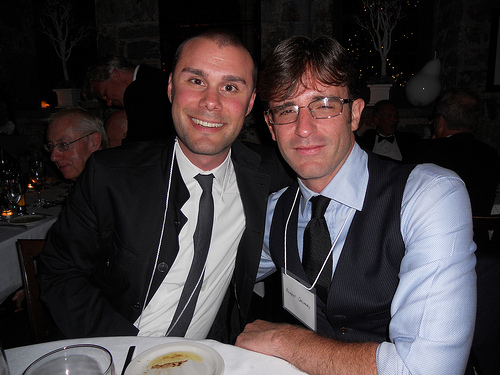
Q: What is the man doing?
A: Smiling.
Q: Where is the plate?
A: On the table.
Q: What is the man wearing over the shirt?
A: A vest.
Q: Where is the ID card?
A: On the man's neck.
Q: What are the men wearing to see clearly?
A: Eyeglasses.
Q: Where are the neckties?
A: On the men's neck.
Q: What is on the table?
A: A plate and utensils.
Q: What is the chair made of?
A: Wood.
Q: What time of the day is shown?
A: Nighttime.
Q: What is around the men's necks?
A: Ties.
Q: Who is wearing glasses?
A: Man on right.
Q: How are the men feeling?
A: Happy.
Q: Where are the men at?
A: A party.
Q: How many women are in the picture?
A: 0.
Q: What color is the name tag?
A: White.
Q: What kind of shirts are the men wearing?
A: Collared shirts.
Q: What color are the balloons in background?
A: White.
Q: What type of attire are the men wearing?
A: Formal.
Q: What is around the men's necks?
A: Tie's.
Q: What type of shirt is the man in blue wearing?
A: A dress shirt.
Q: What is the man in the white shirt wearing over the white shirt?
A: A suit jacket.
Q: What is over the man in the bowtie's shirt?
A: A suit jacket.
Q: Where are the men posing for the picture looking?
A: At the camera.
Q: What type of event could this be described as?
A: A black tie event.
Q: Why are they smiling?
A: They are happy.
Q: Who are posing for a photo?
A: The two men.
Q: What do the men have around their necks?
A: Ties.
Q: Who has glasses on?
A: The man on the right.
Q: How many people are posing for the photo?
A: Two.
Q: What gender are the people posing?
A: Male.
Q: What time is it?
A: Nighttime.